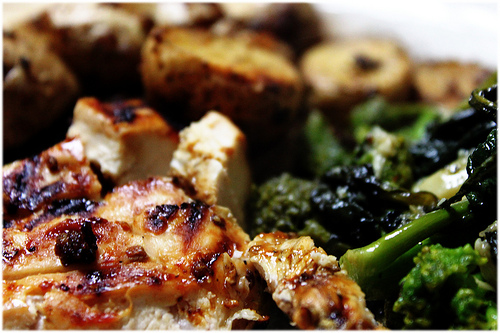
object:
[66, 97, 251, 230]
chicken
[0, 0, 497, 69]
plate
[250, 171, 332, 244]
broccoli floret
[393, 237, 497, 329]
broccoli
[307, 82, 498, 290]
spinach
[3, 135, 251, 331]
chicken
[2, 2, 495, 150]
potatoes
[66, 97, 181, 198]
chunk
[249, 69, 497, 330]
green vegetables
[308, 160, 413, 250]
brussel sprouts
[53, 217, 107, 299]
dark spot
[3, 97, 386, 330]
chicken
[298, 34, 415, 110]
potato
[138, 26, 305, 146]
potato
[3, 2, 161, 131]
potato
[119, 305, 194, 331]
interior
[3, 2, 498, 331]
food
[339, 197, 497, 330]
broccoli